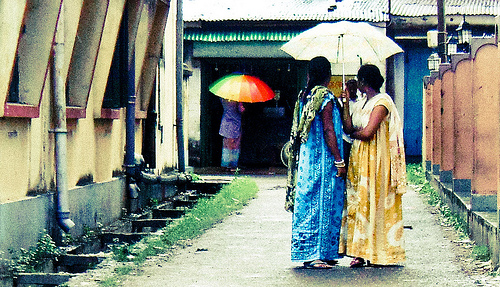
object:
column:
[19, 0, 62, 105]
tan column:
[438, 62, 452, 183]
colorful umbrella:
[205, 71, 273, 105]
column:
[448, 52, 474, 192]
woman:
[217, 97, 246, 173]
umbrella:
[279, 19, 404, 105]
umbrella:
[206, 73, 278, 103]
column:
[468, 35, 500, 211]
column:
[134, 0, 169, 110]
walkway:
[64, 166, 498, 287]